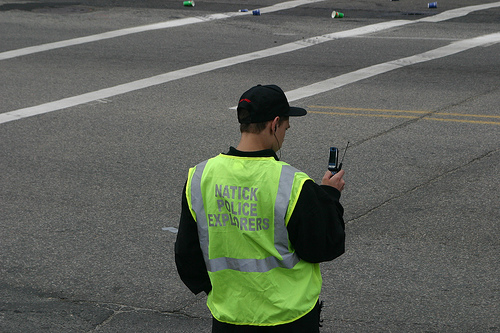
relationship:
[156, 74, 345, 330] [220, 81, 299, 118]
man has hat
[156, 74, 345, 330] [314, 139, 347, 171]
man has phone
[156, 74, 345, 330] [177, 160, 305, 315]
man has vest